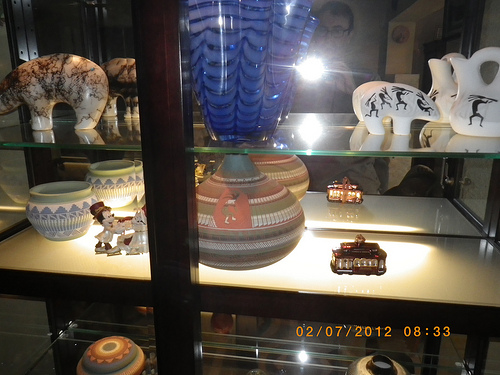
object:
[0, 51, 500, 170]
figures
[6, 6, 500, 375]
photo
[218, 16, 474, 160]
mirror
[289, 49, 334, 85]
flash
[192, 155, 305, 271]
pottery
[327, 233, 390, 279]
trolley toy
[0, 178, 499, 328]
shelf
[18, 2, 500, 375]
wall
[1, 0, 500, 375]
cabinet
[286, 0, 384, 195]
man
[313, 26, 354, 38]
glasses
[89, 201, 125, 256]
mickey mouse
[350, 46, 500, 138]
items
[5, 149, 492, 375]
hutch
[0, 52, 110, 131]
bear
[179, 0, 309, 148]
glass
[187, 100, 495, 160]
shelf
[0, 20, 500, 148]
objects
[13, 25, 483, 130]
objects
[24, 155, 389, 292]
objects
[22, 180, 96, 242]
bowl